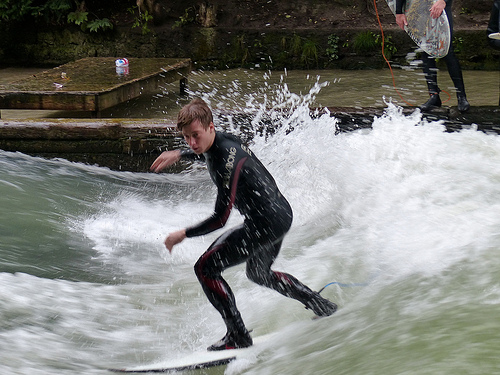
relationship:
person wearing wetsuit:
[157, 101, 345, 347] [173, 135, 342, 351]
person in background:
[388, 0, 470, 112] [3, 1, 495, 164]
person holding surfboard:
[388, 0, 470, 112] [389, 2, 453, 61]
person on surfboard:
[157, 101, 345, 347] [113, 264, 402, 372]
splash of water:
[180, 73, 452, 160] [4, 127, 500, 374]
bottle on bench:
[113, 54, 133, 72] [1, 56, 191, 93]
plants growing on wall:
[5, 0, 204, 43] [3, 2, 500, 56]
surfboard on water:
[113, 264, 402, 372] [4, 127, 500, 374]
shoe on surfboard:
[209, 331, 254, 348] [113, 264, 402, 372]